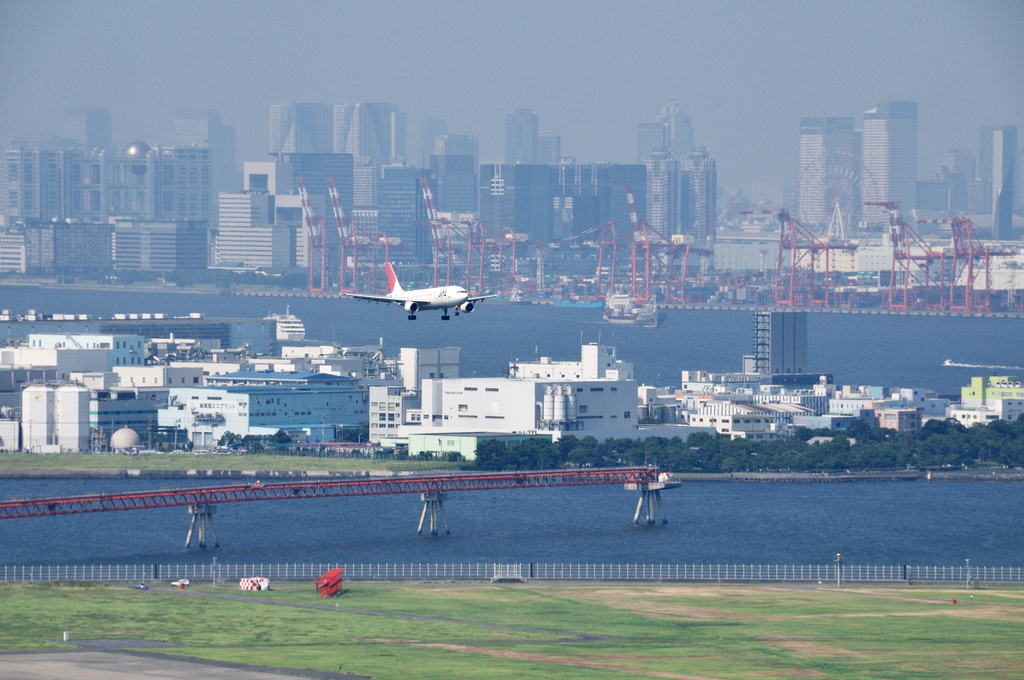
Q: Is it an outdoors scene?
A: Yes, it is outdoors.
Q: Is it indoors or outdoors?
A: It is outdoors.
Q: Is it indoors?
A: No, it is outdoors.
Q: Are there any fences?
A: Yes, there is a fence.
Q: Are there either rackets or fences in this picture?
A: Yes, there is a fence.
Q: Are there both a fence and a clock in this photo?
A: No, there is a fence but no clocks.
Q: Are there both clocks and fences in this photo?
A: No, there is a fence but no clocks.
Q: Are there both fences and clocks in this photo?
A: No, there is a fence but no clocks.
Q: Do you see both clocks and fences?
A: No, there is a fence but no clocks.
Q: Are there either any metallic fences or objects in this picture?
A: Yes, there is a metal fence.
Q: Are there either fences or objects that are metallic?
A: Yes, the fence is metallic.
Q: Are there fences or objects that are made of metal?
A: Yes, the fence is made of metal.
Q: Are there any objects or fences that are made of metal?
A: Yes, the fence is made of metal.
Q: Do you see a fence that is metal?
A: Yes, there is a metal fence.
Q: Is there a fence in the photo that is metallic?
A: Yes, there is a fence that is metallic.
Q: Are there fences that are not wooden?
A: Yes, there is a metallic fence.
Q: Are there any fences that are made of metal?
A: Yes, there is a fence that is made of metal.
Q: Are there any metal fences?
A: Yes, there is a fence that is made of metal.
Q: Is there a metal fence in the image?
A: Yes, there is a fence that is made of metal.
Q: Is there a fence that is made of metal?
A: Yes, there is a fence that is made of metal.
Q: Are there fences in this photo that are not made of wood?
A: Yes, there is a fence that is made of metal.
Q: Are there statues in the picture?
A: No, there are no statues.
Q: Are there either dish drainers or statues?
A: No, there are no statues or dish drainers.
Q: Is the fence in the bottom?
A: Yes, the fence is in the bottom of the image.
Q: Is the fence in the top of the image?
A: No, the fence is in the bottom of the image.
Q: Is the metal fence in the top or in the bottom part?
A: The fence is in the bottom of the image.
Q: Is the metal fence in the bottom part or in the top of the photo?
A: The fence is in the bottom of the image.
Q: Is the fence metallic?
A: Yes, the fence is metallic.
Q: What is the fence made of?
A: The fence is made of metal.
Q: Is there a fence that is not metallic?
A: No, there is a fence but it is metallic.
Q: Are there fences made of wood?
A: No, there is a fence but it is made of metal.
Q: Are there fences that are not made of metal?
A: No, there is a fence but it is made of metal.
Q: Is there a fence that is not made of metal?
A: No, there is a fence but it is made of metal.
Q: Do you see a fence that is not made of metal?
A: No, there is a fence but it is made of metal.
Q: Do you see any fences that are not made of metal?
A: No, there is a fence but it is made of metal.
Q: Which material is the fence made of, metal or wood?
A: The fence is made of metal.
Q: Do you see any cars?
A: No, there are no cars.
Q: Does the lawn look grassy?
A: Yes, the lawn is grassy.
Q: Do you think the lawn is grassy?
A: Yes, the lawn is grassy.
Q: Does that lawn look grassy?
A: Yes, the lawn is grassy.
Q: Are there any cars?
A: No, there are no cars.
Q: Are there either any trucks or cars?
A: No, there are no cars or trucks.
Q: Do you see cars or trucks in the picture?
A: No, there are no cars or trucks.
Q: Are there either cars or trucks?
A: No, there are no cars or trucks.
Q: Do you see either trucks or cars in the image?
A: No, there are no cars or trucks.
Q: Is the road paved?
A: Yes, the road is paved.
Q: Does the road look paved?
A: Yes, the road is paved.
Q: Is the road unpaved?
A: No, the road is paved.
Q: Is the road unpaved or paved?
A: The road is paved.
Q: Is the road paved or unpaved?
A: The road is paved.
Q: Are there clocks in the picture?
A: No, there are no clocks.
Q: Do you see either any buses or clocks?
A: No, there are no clocks or buses.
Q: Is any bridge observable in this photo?
A: Yes, there is a bridge.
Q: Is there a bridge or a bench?
A: Yes, there is a bridge.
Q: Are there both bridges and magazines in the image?
A: No, there is a bridge but no magazines.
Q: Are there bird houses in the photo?
A: No, there are no bird houses.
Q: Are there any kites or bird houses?
A: No, there are no bird houses or kites.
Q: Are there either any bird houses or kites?
A: No, there are no bird houses or kites.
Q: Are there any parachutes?
A: No, there are no parachutes.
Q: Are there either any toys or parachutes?
A: No, there are no parachutes or toys.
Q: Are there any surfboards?
A: No, there are no surfboards.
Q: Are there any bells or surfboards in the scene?
A: No, there are no surfboards or bells.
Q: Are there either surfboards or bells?
A: No, there are no surfboards or bells.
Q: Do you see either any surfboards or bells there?
A: No, there are no surfboards or bells.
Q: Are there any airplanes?
A: Yes, there is an airplane.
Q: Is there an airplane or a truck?
A: Yes, there is an airplane.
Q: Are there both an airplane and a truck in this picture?
A: No, there is an airplane but no trucks.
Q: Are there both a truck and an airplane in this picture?
A: No, there is an airplane but no trucks.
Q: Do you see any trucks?
A: No, there are no trucks.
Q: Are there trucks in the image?
A: No, there are no trucks.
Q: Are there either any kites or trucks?
A: No, there are no trucks or kites.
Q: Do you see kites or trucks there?
A: No, there are no trucks or kites.